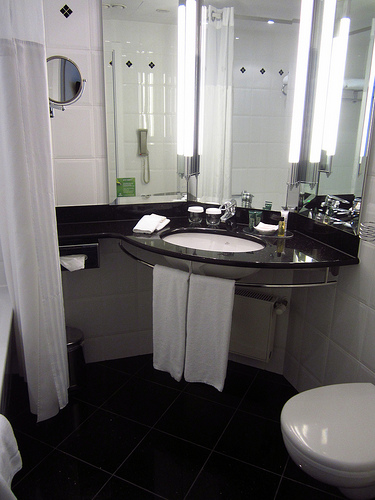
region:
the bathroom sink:
[154, 222, 271, 281]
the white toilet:
[275, 379, 373, 498]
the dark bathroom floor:
[115, 405, 234, 499]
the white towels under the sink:
[145, 256, 231, 400]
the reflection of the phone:
[135, 125, 154, 183]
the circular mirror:
[41, 51, 84, 114]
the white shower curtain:
[2, 0, 70, 421]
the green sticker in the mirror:
[118, 175, 137, 199]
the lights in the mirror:
[176, 0, 309, 185]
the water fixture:
[217, 200, 237, 229]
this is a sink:
[159, 226, 259, 253]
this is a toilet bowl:
[274, 378, 371, 487]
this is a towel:
[185, 278, 230, 387]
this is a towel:
[150, 263, 181, 375]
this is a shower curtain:
[0, 0, 72, 422]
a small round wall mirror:
[34, 52, 85, 106]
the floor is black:
[5, 348, 344, 494]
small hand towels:
[131, 211, 169, 237]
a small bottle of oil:
[273, 215, 289, 235]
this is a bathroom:
[2, 3, 370, 495]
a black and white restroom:
[1, 1, 371, 498]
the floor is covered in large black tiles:
[16, 371, 283, 494]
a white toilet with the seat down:
[277, 375, 373, 495]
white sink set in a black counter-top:
[162, 222, 315, 256]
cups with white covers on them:
[181, 205, 228, 228]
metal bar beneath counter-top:
[231, 237, 340, 295]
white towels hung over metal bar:
[142, 258, 266, 393]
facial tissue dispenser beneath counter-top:
[58, 220, 121, 275]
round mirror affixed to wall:
[44, 48, 86, 123]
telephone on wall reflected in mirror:
[99, 94, 165, 181]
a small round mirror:
[28, 42, 89, 114]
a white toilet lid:
[281, 371, 374, 477]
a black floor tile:
[121, 416, 202, 499]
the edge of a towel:
[0, 411, 26, 494]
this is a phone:
[133, 126, 161, 186]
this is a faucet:
[217, 185, 238, 230]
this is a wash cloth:
[132, 200, 176, 242]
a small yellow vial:
[274, 212, 291, 243]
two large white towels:
[130, 248, 253, 411]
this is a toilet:
[267, 367, 374, 492]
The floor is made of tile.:
[71, 425, 221, 498]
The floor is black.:
[88, 434, 221, 498]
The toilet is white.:
[271, 374, 373, 494]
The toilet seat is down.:
[273, 373, 373, 497]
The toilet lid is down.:
[268, 377, 373, 496]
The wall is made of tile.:
[303, 303, 362, 366]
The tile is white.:
[308, 301, 364, 367]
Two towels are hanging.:
[136, 262, 243, 403]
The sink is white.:
[156, 220, 272, 265]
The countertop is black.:
[58, 213, 282, 306]